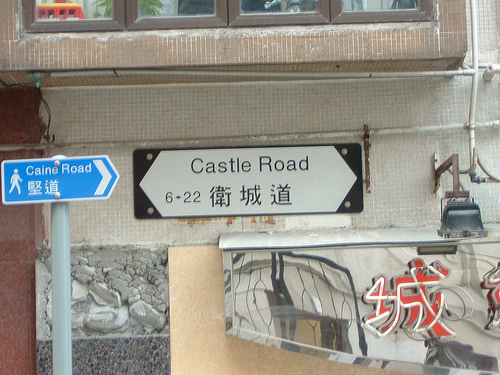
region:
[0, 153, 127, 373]
this is a street sign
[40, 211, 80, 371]
this is a pole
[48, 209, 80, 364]
the pole is metallic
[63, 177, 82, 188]
the sign is blue in color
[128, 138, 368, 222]
this is a signboard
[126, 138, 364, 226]
the signboard is rectangular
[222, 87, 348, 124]
this is a wall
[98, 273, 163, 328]
these are some stones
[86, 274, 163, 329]
the stones are grey in color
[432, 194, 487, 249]
this is a headlight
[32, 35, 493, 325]
picture taken outdoors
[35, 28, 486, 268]
picture taken during the day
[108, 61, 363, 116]
the building has tile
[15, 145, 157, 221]
a sign says Caine Road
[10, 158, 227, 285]
the arrow is pointing to the right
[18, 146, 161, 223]
the sign is blue and white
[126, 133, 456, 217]
sign says Castle Road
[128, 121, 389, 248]
the sign is black and white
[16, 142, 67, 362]
a metal pole holding on the sign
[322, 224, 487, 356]
chinese writing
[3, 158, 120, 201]
blue and white road sign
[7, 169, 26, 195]
symbol of a person walking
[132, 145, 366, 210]
black and white sign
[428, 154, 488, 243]
light fixture on building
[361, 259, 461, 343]
red and white neon sign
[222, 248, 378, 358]
reflection on the metal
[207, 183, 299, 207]
three oriental characters on sign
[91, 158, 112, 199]
arrow on street sign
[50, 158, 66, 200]
two metal rivets on sign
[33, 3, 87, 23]
reflection of red vehicle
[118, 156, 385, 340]
picture taken outside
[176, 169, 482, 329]
chinese writing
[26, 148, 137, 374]
a blue sign on a post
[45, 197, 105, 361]
the post is metal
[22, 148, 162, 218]
the sign has a white arrow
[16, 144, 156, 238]
the sign says Caine Road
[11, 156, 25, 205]
a picture of a person walking on the sign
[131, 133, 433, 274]
another sign is black and white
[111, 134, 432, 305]
the sign says Castle Road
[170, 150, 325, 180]
Castle Road on a sign.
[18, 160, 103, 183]
Caine Road on a sign.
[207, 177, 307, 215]
Chinese writing on the sign.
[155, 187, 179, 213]
6 on the sign.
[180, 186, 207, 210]
22 on the sign.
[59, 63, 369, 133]
The wall is made of small brick.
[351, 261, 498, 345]
Graffiti on the banner.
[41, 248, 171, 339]
Rocks on the wall.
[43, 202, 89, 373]
The pole is grey.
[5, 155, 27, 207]
Person on the sign.